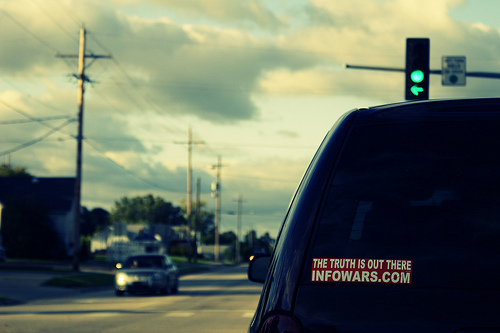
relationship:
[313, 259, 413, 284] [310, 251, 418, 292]
letters are on bumper sticker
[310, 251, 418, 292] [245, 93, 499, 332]
bumper sticker on car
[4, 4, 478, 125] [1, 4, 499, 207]
clouds are in sky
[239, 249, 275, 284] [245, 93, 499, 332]
side mirror on car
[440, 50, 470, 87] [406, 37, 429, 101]
sign by trafficlight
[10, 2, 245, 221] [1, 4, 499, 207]
powerlines are in sky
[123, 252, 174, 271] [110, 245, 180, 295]
windshield on car front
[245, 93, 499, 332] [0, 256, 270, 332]
car in street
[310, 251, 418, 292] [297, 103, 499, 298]
bumper sticker in window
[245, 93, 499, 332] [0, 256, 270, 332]
car on street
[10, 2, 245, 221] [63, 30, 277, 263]
powerlines are on utility poles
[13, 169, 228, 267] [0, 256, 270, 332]
houses are by street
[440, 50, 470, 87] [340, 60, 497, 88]
sign on pole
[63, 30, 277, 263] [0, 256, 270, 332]
utility poles are in street